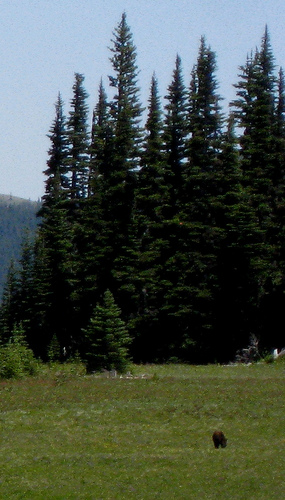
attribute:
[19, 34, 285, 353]
trees — green, tall, pointy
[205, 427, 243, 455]
bear — big, small, brown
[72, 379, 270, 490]
grass — green, dark, yellow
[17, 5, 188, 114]
sky — blue, clear